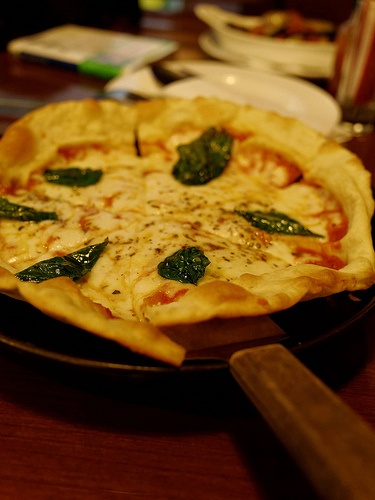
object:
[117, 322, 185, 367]
crust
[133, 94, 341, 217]
slice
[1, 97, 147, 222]
slice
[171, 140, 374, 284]
slice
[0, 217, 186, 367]
slice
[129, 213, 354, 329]
slice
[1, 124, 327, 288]
toppings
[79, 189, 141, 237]
cheese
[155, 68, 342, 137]
plate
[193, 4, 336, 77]
plate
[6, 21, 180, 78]
book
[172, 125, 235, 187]
spinach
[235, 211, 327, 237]
basil leaf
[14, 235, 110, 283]
basil leaf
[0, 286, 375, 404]
pizza dish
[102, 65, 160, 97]
napkin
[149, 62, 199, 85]
utensils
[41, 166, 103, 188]
leaf spice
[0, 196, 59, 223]
leaf spice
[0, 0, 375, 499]
table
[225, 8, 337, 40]
food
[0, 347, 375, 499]
shadow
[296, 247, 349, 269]
tomato sauce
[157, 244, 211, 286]
spinach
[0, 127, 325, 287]
herbs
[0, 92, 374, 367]
pizza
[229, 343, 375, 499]
handle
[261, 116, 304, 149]
crust